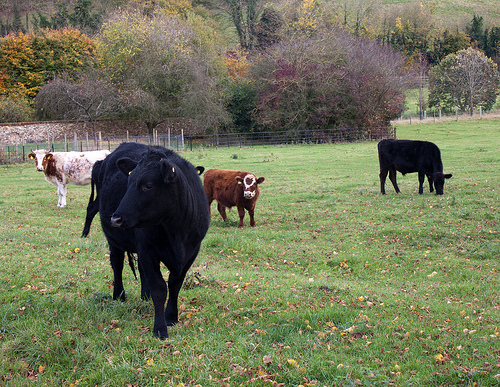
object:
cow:
[80, 140, 213, 341]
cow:
[202, 168, 267, 230]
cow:
[26, 146, 112, 209]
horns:
[29, 147, 36, 156]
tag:
[30, 156, 33, 160]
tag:
[237, 181, 242, 185]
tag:
[129, 171, 133, 176]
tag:
[171, 167, 175, 173]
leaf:
[285, 357, 301, 369]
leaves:
[352, 302, 358, 303]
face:
[31, 149, 54, 173]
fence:
[0, 125, 187, 166]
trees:
[0, 14, 7, 35]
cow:
[376, 137, 453, 195]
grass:
[0, 122, 500, 384]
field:
[0, 119, 500, 387]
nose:
[110, 213, 125, 228]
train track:
[0, 120, 73, 126]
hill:
[0, 116, 78, 148]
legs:
[137, 246, 170, 341]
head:
[107, 149, 181, 231]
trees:
[411, 58, 427, 122]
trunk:
[418, 72, 424, 122]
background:
[0, 0, 499, 164]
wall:
[0, 120, 150, 144]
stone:
[0, 122, 69, 145]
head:
[234, 173, 266, 200]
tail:
[88, 161, 98, 204]